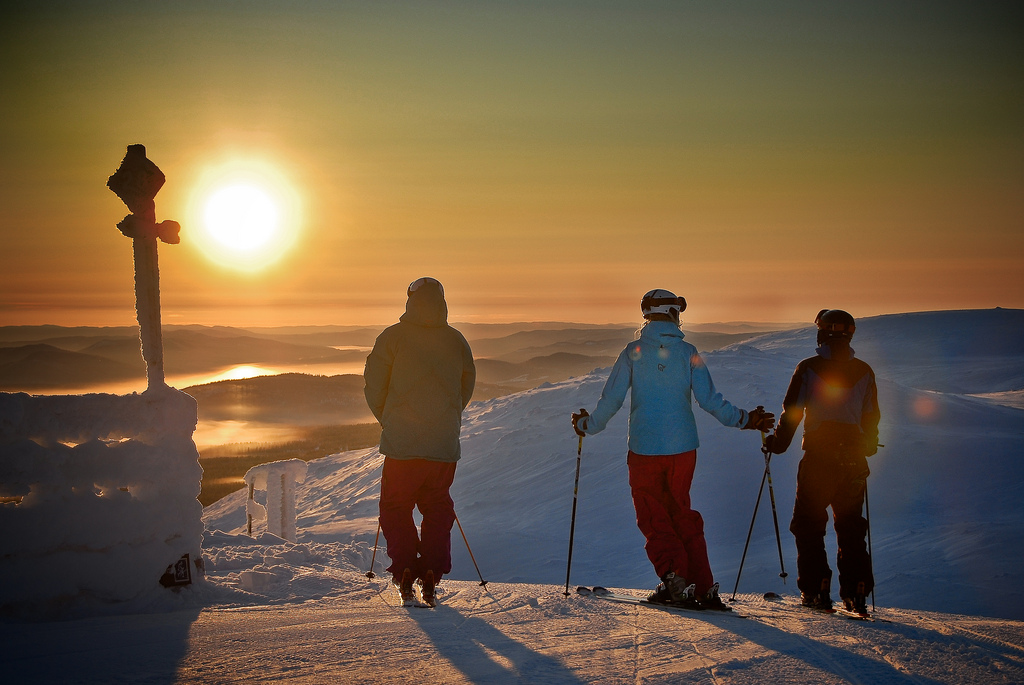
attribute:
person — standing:
[363, 276, 475, 606]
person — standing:
[573, 288, 775, 603]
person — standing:
[763, 309, 881, 611]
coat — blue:
[581, 319, 749, 459]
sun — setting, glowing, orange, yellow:
[178, 152, 307, 275]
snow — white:
[12, 307, 1023, 679]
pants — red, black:
[381, 457, 455, 580]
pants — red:
[624, 452, 716, 589]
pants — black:
[789, 454, 876, 608]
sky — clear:
[0, 4, 1021, 334]